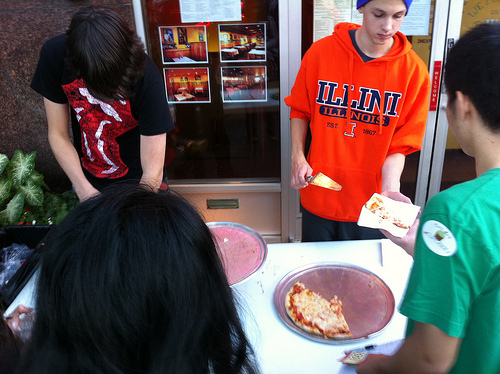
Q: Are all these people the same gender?
A: No, they are both male and female.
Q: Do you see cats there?
A: No, there are no cats.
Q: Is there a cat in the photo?
A: No, there are no cats.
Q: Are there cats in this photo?
A: No, there are no cats.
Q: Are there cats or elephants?
A: No, there are no cats or elephants.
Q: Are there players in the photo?
A: No, there are no players.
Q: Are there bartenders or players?
A: No, there are no players or bartenders.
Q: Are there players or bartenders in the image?
A: No, there are no players or bartenders.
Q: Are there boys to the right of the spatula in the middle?
A: Yes, there is a boy to the right of the spatula.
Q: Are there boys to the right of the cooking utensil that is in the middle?
A: Yes, there is a boy to the right of the spatula.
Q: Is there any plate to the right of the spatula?
A: No, there is a boy to the right of the spatula.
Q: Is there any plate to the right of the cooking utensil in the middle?
A: No, there is a boy to the right of the spatula.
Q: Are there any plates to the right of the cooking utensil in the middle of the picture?
A: No, there is a boy to the right of the spatula.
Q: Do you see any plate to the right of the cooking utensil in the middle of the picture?
A: No, there is a boy to the right of the spatula.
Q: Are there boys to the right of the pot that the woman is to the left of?
A: Yes, there is a boy to the right of the pot.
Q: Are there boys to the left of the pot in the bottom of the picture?
A: No, the boy is to the right of the pot.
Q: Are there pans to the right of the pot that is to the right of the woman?
A: No, there is a boy to the right of the pot.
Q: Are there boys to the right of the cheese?
A: Yes, there is a boy to the right of the cheese.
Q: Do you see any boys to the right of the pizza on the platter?
A: Yes, there is a boy to the right of the pizza.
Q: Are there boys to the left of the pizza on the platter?
A: No, the boy is to the right of the pizza.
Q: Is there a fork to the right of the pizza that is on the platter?
A: No, there is a boy to the right of the pizza.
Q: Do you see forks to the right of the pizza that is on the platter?
A: No, there is a boy to the right of the pizza.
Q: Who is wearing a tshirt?
A: The boy is wearing a tshirt.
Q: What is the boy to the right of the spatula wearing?
A: The boy is wearing a tshirt.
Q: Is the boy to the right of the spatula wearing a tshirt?
A: Yes, the boy is wearing a tshirt.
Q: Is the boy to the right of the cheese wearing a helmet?
A: No, the boy is wearing a tshirt.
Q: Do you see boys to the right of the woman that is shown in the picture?
A: Yes, there is a boy to the right of the woman.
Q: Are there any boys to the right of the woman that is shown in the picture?
A: Yes, there is a boy to the right of the woman.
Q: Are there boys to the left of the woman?
A: No, the boy is to the right of the woman.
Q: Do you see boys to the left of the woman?
A: No, the boy is to the right of the woman.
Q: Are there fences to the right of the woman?
A: No, there is a boy to the right of the woman.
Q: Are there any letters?
A: Yes, there are letters.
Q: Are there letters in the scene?
A: Yes, there are letters.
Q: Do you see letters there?
A: Yes, there are letters.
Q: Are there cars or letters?
A: Yes, there are letters.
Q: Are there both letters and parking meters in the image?
A: No, there are letters but no parking meters.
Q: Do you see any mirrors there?
A: No, there are no mirrors.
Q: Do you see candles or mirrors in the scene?
A: No, there are no mirrors or candles.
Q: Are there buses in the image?
A: No, there are no buses.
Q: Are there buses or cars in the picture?
A: No, there are no buses or cars.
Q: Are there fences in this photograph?
A: No, there are no fences.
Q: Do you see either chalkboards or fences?
A: No, there are no fences or chalkboards.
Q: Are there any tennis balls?
A: No, there are no tennis balls.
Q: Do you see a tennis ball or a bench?
A: No, there are no tennis balls or benches.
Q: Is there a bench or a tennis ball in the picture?
A: No, there are no tennis balls or benches.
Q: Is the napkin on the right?
A: Yes, the napkin is on the right of the image.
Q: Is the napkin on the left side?
A: No, the napkin is on the right of the image.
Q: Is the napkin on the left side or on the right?
A: The napkin is on the right of the image.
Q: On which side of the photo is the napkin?
A: The napkin is on the right of the image.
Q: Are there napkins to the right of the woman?
A: Yes, there is a napkin to the right of the woman.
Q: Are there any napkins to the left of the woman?
A: No, the napkin is to the right of the woman.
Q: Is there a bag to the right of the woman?
A: No, there is a napkin to the right of the woman.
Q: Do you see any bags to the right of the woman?
A: No, there is a napkin to the right of the woman.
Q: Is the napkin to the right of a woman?
A: Yes, the napkin is to the right of a woman.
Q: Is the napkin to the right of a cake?
A: No, the napkin is to the right of a woman.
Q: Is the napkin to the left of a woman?
A: No, the napkin is to the right of a woman.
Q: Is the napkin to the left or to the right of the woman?
A: The napkin is to the right of the woman.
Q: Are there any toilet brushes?
A: No, there are no toilet brushes.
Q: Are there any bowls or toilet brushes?
A: No, there are no toilet brushes or bowls.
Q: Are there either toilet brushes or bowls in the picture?
A: No, there are no toilet brushes or bowls.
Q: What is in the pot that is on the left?
A: The plant is in the pot.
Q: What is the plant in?
A: The plant is in the pot.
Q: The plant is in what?
A: The plant is in the pot.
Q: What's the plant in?
A: The plant is in the pot.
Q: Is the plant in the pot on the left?
A: Yes, the plant is in the pot.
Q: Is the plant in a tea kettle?
A: No, the plant is in the pot.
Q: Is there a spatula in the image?
A: Yes, there is a spatula.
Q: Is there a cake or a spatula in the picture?
A: Yes, there is a spatula.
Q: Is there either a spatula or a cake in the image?
A: Yes, there is a spatula.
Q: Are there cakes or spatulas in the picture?
A: Yes, there is a spatula.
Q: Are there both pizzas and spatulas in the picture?
A: Yes, there are both a spatula and a pizza.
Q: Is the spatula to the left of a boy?
A: Yes, the spatula is to the left of a boy.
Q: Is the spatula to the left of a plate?
A: No, the spatula is to the left of a boy.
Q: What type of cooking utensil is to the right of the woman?
A: The cooking utensil is a spatula.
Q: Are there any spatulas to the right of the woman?
A: Yes, there is a spatula to the right of the woman.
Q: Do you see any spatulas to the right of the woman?
A: Yes, there is a spatula to the right of the woman.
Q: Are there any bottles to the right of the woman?
A: No, there is a spatula to the right of the woman.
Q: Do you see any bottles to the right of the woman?
A: No, there is a spatula to the right of the woman.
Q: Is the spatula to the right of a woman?
A: Yes, the spatula is to the right of a woman.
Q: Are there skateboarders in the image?
A: No, there are no skateboarders.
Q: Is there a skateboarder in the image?
A: No, there are no skateboarders.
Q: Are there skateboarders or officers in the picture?
A: No, there are no skateboarders or officers.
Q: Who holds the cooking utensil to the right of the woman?
A: The boy holds the spatula.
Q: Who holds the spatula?
A: The boy holds the spatula.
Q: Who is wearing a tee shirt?
A: The boy is wearing a tee shirt.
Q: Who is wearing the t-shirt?
A: The boy is wearing a tee shirt.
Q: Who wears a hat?
A: The boy wears a hat.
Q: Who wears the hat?
A: The boy wears a hat.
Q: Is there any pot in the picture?
A: Yes, there is a pot.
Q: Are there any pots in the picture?
A: Yes, there is a pot.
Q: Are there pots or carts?
A: Yes, there is a pot.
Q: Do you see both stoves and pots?
A: No, there is a pot but no stoves.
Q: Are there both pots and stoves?
A: No, there is a pot but no stoves.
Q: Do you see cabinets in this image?
A: No, there are no cabinets.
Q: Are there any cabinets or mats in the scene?
A: No, there are no cabinets or mats.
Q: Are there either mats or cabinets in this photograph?
A: No, there are no cabinets or mats.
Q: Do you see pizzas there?
A: Yes, there is a pizza.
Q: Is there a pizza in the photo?
A: Yes, there is a pizza.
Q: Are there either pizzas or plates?
A: Yes, there is a pizza.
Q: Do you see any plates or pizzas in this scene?
A: Yes, there is a pizza.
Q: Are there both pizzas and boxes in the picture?
A: No, there is a pizza but no boxes.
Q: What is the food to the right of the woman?
A: The food is a pizza.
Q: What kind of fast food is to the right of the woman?
A: The food is a pizza.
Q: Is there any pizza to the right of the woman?
A: Yes, there is a pizza to the right of the woman.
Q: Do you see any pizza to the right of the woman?
A: Yes, there is a pizza to the right of the woman.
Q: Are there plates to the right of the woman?
A: No, there is a pizza to the right of the woman.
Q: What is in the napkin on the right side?
A: The pizza is in the napkin.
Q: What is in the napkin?
A: The pizza is in the napkin.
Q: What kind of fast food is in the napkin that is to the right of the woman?
A: The food is a pizza.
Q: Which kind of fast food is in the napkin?
A: The food is a pizza.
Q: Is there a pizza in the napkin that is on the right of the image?
A: Yes, there is a pizza in the napkin.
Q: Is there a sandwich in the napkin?
A: No, there is a pizza in the napkin.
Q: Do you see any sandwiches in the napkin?
A: No, there is a pizza in the napkin.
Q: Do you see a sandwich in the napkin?
A: No, there is a pizza in the napkin.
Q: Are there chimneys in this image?
A: No, there are no chimneys.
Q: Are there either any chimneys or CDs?
A: No, there are no chimneys or cds.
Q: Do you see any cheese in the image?
A: Yes, there is cheese.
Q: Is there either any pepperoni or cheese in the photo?
A: Yes, there is cheese.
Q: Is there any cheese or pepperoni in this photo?
A: Yes, there is cheese.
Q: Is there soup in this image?
A: No, there is no soup.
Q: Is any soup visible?
A: No, there is no soup.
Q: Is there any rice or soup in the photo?
A: No, there are no soup or rice.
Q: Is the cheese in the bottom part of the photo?
A: Yes, the cheese is in the bottom of the image.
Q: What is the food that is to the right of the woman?
A: The food is cheese.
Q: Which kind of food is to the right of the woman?
A: The food is cheese.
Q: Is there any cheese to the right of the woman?
A: Yes, there is cheese to the right of the woman.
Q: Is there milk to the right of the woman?
A: No, there is cheese to the right of the woman.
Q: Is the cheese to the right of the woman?
A: Yes, the cheese is to the right of the woman.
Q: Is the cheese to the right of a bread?
A: No, the cheese is to the right of the woman.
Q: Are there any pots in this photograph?
A: Yes, there is a pot.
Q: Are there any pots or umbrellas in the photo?
A: Yes, there is a pot.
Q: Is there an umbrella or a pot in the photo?
A: Yes, there is a pot.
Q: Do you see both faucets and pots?
A: No, there is a pot but no faucets.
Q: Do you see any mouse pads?
A: No, there are no mouse pads.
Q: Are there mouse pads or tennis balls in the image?
A: No, there are no mouse pads or tennis balls.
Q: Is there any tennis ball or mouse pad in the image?
A: No, there are no mouse pads or tennis balls.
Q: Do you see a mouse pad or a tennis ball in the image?
A: No, there are no mouse pads or tennis balls.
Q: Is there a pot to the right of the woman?
A: Yes, there is a pot to the right of the woman.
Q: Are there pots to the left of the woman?
A: No, the pot is to the right of the woman.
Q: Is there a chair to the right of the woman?
A: No, there is a pot to the right of the woman.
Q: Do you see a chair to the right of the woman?
A: No, there is a pot to the right of the woman.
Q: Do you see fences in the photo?
A: No, there are no fences.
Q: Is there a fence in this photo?
A: No, there are no fences.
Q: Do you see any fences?
A: No, there are no fences.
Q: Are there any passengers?
A: No, there are no passengers.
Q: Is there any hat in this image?
A: Yes, there is a hat.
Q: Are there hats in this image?
A: Yes, there is a hat.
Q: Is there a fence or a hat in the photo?
A: Yes, there is a hat.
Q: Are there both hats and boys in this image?
A: Yes, there are both a hat and a boy.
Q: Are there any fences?
A: No, there are no fences.